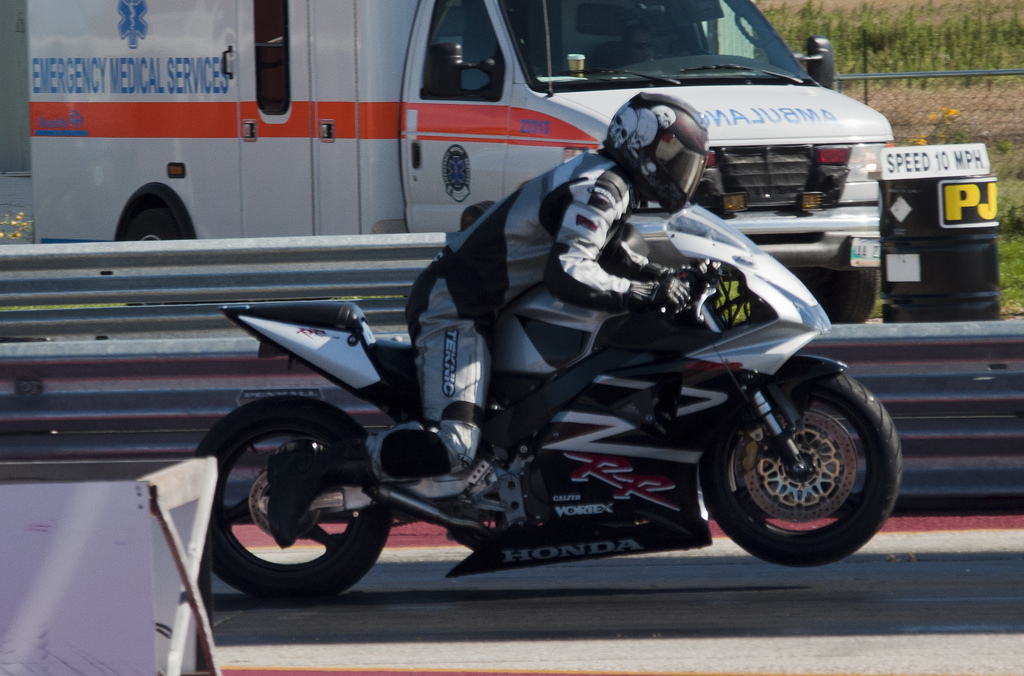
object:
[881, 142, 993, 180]
signs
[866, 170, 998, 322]
barrel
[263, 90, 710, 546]
man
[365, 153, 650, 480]
jumpsuit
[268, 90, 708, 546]
racer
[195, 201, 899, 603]
bike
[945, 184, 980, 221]
letter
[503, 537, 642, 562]
word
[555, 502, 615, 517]
word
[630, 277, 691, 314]
hand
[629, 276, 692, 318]
glove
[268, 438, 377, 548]
boot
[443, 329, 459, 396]
logo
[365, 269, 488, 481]
pants